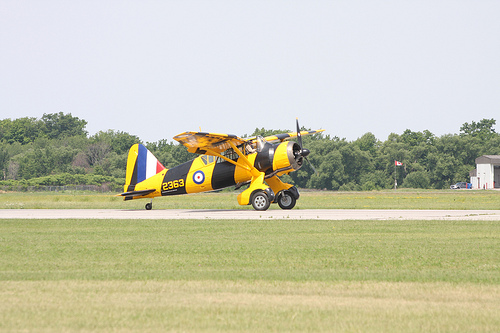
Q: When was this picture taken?
A: During the day.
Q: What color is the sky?
A: Blue.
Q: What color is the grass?
A: Green.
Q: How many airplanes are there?
A: One.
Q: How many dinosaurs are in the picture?
A: Zero.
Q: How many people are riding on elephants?
A: Zero.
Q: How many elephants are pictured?
A: Zero.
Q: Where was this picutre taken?
A: At an airport.